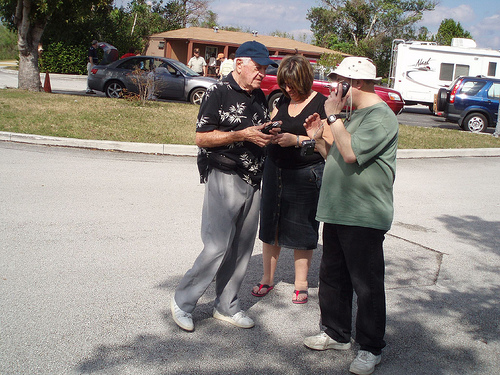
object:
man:
[302, 56, 399, 374]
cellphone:
[336, 80, 351, 97]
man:
[170, 39, 283, 331]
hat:
[235, 40, 279, 68]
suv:
[437, 74, 500, 134]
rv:
[386, 37, 500, 112]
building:
[144, 27, 356, 80]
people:
[188, 47, 208, 76]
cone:
[44, 70, 52, 93]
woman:
[250, 55, 329, 304]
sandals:
[251, 282, 308, 304]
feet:
[292, 290, 309, 304]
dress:
[257, 88, 328, 251]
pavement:
[1, 139, 499, 374]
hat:
[326, 56, 383, 81]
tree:
[317, 43, 365, 73]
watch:
[326, 113, 341, 125]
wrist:
[326, 112, 340, 123]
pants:
[318, 223, 387, 356]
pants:
[173, 167, 261, 317]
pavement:
[1, 71, 499, 132]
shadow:
[76, 210, 500, 375]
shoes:
[304, 331, 383, 374]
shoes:
[170, 295, 256, 332]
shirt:
[314, 101, 399, 231]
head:
[335, 57, 375, 105]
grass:
[0, 85, 499, 147]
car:
[86, 54, 220, 104]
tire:
[104, 79, 125, 99]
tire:
[190, 88, 207, 105]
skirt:
[257, 155, 326, 250]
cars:
[257, 55, 404, 116]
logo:
[402, 57, 438, 89]